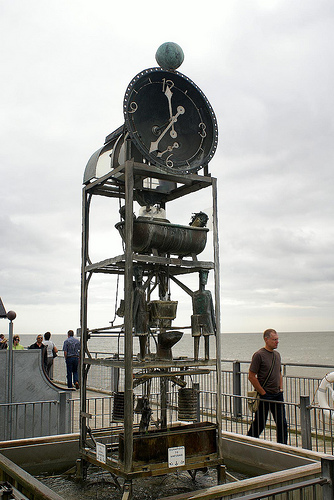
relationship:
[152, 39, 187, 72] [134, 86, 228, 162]
object on clock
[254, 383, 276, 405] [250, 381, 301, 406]
hands in pocket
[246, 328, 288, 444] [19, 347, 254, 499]
man on boat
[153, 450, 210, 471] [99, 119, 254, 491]
sign on exhibit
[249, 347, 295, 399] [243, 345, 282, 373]
strap on shoulder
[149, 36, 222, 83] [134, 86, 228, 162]
ball on clock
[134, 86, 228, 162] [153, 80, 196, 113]
clock has hand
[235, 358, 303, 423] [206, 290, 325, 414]
arm on man